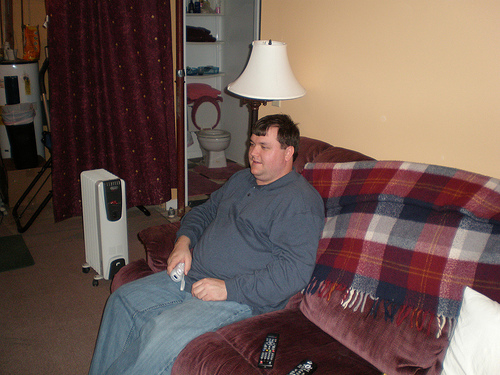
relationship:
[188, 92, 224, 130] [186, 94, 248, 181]
cover on toilet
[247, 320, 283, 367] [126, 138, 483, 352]
controller on couch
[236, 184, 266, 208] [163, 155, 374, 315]
button on shirt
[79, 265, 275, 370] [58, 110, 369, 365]
jeans on man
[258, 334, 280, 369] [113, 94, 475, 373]
controller on sofa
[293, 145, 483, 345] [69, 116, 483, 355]
blanket on sofa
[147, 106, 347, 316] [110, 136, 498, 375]
man sitting couch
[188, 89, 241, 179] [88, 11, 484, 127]
toilet in background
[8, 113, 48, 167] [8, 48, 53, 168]
can near heater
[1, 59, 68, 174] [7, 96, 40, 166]
heater behind can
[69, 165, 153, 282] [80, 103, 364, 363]
object near man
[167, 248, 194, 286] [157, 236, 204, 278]
wiimote in hand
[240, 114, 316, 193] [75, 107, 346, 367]
head of person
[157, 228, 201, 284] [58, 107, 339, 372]
hand of person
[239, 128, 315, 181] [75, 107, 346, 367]
face of person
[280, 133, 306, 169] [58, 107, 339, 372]
ear of person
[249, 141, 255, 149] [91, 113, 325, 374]
eye of man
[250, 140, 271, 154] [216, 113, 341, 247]
eye of a person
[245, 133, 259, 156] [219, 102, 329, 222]
eye of a person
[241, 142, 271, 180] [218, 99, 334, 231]
nose of a person